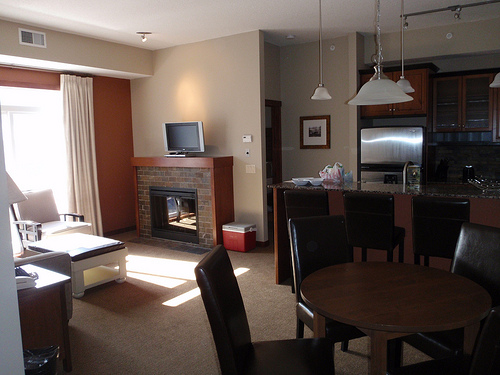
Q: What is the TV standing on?
A: Fireplace.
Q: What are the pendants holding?
A: Bulbs.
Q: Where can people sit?
A: Dining chairs.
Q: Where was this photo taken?
A: In a living room.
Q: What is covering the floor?
A: Carpet.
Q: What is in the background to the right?
A: The kitchen.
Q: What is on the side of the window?
A: Curtains.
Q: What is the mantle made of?
A: Wood.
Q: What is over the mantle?
A: A vent.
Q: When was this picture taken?
A: In the daytime.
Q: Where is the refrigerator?
A: Kitchen.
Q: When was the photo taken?
A: Daytime.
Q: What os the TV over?
A: Fireplace.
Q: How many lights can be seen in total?
A: Eight.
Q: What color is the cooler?
A: Red.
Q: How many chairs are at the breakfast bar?
A: Three.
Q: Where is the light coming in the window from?
A: Sun.